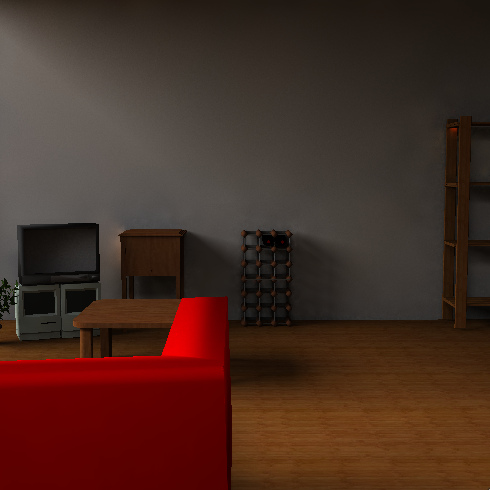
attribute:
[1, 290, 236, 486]
sofa — red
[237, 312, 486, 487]
tile — brown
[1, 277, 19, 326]
plant — green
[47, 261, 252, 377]
table — wooden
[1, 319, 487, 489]
floor — wooden, parquet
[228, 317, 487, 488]
floor — wooden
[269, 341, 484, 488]
floor — wooden, parquet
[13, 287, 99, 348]
stand — white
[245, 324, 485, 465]
flooring — hardwood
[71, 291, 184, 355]
table — coffee, brown, wooden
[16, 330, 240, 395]
sofa — orange.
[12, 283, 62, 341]
monitor — old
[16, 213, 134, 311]
television — black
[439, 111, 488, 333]
stand — brown, wooden, shelved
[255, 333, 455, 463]
floor — wooden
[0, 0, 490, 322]
wall — white